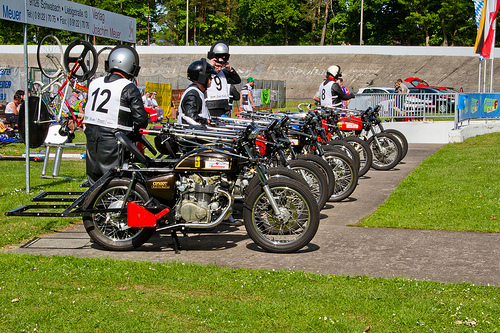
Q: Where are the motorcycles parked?
A: Inside a patch of green grass.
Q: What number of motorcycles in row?
A: Ten.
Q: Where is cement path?
A: In the grass.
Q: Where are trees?
A: Behind wall.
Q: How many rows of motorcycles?
A: One row.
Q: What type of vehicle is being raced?
A: Motorcycles.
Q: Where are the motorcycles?
A: Grey sidewalk.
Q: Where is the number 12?
A: On nearest racer.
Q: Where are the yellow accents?
A: On nearest motorcycle.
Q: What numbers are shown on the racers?
A: 12, 9, 8.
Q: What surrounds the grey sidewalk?
A: Grass.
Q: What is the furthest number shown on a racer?
A: 8.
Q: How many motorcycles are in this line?
A: Ten.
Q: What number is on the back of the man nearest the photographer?
A: Twelve.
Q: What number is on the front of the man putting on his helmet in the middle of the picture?
A: Nine.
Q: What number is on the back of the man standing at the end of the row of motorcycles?
A: Eight.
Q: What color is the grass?
A: Green.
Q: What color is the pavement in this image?
A: Grey.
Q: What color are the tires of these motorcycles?
A: Black.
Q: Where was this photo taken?
A: At a motorcycle race.